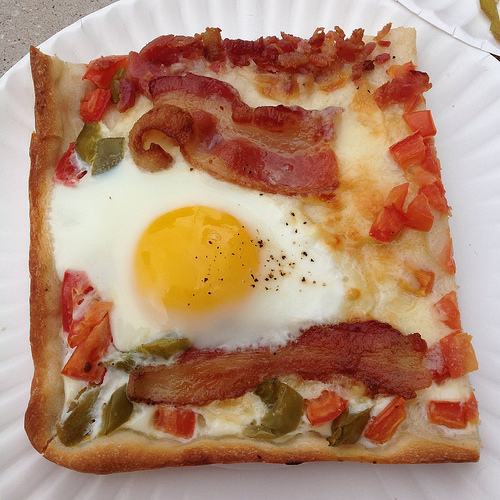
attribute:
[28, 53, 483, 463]
pizza — square, crispy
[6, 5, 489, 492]
dish — white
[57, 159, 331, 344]
egg — sunny side up, soft boiled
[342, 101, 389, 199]
cheese — melted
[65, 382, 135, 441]
pepper — cubed, green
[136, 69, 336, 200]
bacon — sliced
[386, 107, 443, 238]
tomato — red, diced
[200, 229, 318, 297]
pepper — sprinkled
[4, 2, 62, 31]
countertop — grey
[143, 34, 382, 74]
bacon — crispy, crumbled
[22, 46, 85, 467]
crust — golden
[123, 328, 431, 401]
bacon — cooked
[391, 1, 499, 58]
paper plates — overlapping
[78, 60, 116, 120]
vegetables — red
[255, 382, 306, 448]
green vegetable — diced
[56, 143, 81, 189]
pepper — red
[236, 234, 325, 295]
pepper — diced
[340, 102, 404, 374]
cheese — brown, melted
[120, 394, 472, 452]
peppers — red, green